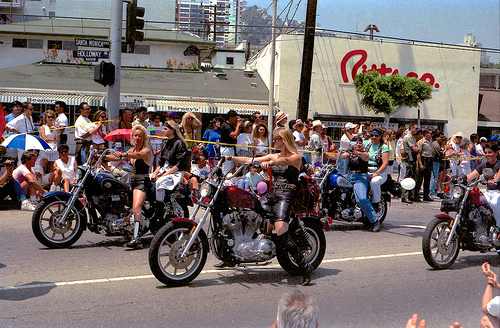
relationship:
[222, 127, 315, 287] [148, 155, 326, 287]
woman riding motorcycle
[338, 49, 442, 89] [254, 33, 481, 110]
sign for store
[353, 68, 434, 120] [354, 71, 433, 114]
tree with leaves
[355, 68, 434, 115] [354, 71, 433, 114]
lots of leaves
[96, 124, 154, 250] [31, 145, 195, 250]
woman riding a harley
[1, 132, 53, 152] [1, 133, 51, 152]
blue and white umbrella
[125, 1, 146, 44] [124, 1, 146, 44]
traffic signal black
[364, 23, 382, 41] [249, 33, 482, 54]
object on top of roof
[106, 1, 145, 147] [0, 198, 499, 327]
light on side of street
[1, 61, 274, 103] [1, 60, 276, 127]
top of building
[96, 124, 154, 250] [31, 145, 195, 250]
woman riding motorcycle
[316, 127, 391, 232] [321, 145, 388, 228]
couple riding motorcycle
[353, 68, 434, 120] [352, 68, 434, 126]
tree in background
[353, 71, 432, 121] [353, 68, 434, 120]
small green tree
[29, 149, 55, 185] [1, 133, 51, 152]
person holding an umbrella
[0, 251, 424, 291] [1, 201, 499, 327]
line in street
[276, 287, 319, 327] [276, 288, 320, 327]
back of head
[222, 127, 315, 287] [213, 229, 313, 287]
woman wearing boots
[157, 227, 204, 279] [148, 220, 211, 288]
wheel inside wheel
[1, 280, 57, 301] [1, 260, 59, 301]
shadow of someone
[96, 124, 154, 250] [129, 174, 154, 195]
woman wearing skirt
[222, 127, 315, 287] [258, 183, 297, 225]
woman in a skirt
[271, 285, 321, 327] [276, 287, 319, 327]
man has gray hair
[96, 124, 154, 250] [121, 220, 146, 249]
woman wearing boots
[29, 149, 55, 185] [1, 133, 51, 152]
person holding umbrella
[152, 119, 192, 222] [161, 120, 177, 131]
person wearing bandana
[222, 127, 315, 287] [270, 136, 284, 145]
woman wearing sunglasses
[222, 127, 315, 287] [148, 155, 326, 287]
woman on motorcycle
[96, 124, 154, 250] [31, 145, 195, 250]
woman on motorcycle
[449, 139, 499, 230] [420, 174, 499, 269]
woman on motorcycle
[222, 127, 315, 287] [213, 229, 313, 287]
blonde in leather boots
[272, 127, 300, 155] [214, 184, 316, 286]
blonde in leather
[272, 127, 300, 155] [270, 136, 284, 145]
blonde in sunglasses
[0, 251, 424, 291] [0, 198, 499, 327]
line in middle of street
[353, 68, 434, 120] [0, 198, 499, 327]
tree on side of street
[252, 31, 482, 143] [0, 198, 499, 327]
building on side of street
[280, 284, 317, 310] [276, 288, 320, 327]
top of a head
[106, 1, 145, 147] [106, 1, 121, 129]
light on a pole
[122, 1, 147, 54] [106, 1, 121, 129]
street light on a pole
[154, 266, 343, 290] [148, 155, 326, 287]
shadow of motorcycle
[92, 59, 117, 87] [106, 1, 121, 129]
street sign on a pole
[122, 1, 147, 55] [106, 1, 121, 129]
street sign on a pole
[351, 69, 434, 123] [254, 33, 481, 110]
green tree in front of store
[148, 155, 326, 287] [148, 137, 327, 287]
motorcycle with motorcycle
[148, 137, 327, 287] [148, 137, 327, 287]
motorcycle with motorcycle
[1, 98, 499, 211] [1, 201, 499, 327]
audience along side of street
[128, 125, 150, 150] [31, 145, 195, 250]
blonde riding motorcycle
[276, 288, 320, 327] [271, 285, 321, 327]
head of a man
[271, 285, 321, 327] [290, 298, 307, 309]
man with balding spot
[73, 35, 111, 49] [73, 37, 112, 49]
street name street sign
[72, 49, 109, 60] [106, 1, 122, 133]
street-name sign on a pole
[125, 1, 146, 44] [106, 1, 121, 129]
traffic lights on a pole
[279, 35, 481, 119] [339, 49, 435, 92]
storefront with letters